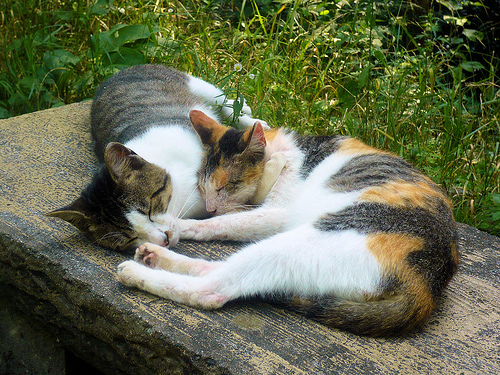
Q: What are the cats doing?
A: Sleeping.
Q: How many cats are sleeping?
A: Two.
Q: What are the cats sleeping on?
A: A Stone board.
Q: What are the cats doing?
A: Cuddling together.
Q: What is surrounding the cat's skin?
A: Fur.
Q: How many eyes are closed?
A: Four.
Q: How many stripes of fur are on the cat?
A: Seven.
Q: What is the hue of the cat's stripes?
A: Dark.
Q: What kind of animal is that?
A: Cats.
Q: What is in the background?
A: Green vegetation.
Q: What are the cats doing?
A: Sleeping together.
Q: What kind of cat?
A: Calico.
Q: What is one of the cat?
A: Tabby.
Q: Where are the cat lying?
A: On a bench.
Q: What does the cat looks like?
A: Connected to each other.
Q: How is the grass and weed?
A: Grass & weeds.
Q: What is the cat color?
A: Orange.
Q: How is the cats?
A: Sleeping sweetly.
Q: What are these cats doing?
A: Sleeping.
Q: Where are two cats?
A: On the concrete block.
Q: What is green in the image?
A: Grass.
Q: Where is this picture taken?
A: Garden.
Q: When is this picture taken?
A: During day time.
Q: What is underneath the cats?
A: Concrete block.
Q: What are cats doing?
A: Laying.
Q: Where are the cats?
A: On bench.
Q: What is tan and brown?
A: Bench.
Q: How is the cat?
A: Striped.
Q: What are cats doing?
A: Sleeping.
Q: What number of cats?
A: Two.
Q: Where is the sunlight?
A: On grass.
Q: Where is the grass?
A: Behind bench.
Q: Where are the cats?
A: On bench.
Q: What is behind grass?
A: Grass.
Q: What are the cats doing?
A: Sleeping.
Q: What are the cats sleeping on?
A: Wooden bench.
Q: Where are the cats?
A: Backyard.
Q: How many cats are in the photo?
A: Two.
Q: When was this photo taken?
A: Daytime.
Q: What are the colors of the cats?
A: White, dark gray and burnt orange.